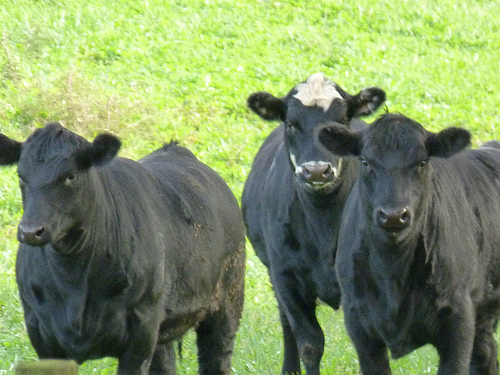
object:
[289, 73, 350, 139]
black and white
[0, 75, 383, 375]
two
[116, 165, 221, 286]
black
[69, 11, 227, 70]
grass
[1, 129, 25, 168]
left ear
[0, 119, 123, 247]
head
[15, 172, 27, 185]
left eye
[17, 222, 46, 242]
nose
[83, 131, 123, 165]
right ear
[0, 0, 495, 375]
field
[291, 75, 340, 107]
white patch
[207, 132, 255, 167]
forward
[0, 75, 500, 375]
still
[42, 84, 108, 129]
brown patch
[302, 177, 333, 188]
open mouth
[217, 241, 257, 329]
dirt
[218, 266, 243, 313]
cow fur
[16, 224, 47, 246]
shiny nose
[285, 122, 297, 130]
eye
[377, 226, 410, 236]
mouth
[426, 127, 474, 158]
ear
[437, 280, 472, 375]
leg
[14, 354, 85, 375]
post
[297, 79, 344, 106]
white spot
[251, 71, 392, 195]
cow head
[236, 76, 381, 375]
black cow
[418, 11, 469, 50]
short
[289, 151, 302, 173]
white markings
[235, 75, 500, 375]
two cows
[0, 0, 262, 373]
left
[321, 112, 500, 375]
black cow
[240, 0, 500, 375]
right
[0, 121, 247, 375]
3 cows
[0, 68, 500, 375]
group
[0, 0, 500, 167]
background